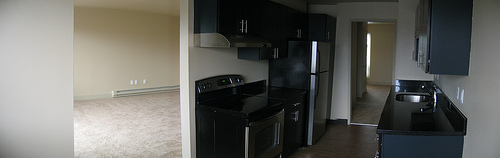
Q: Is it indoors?
A: Yes, it is indoors.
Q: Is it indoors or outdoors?
A: It is indoors.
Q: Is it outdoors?
A: No, it is indoors.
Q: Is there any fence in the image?
A: No, there are no fences.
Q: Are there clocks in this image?
A: No, there are no clocks.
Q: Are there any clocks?
A: No, there are no clocks.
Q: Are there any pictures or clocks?
A: No, there are no clocks or pictures.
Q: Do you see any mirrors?
A: No, there are no mirrors.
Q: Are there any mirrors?
A: No, there are no mirrors.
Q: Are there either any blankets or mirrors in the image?
A: No, there are no mirrors or blankets.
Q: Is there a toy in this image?
A: No, there are no toys.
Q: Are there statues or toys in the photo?
A: No, there are no toys or statues.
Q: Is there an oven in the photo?
A: Yes, there is an oven.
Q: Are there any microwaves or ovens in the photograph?
A: Yes, there is an oven.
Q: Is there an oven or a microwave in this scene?
A: Yes, there is an oven.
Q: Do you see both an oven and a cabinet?
A: Yes, there are both an oven and a cabinet.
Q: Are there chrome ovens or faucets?
A: Yes, there is a chrome oven.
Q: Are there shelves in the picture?
A: No, there are no shelves.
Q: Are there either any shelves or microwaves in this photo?
A: No, there are no shelves or microwaves.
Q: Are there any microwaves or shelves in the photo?
A: No, there are no shelves or microwaves.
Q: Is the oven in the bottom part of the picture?
A: Yes, the oven is in the bottom of the image.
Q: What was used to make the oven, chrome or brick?
A: The oven is made of chrome.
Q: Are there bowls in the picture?
A: No, there are no bowls.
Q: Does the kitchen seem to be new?
A: Yes, the kitchen is new.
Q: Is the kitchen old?
A: No, the kitchen is new.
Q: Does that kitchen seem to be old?
A: No, the kitchen is new.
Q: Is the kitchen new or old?
A: The kitchen is new.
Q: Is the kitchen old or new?
A: The kitchen is new.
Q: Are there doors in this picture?
A: Yes, there are doors.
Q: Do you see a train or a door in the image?
A: Yes, there are doors.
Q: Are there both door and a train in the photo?
A: No, there are doors but no trains.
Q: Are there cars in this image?
A: No, there are no cars.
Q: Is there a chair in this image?
A: No, there are no chairs.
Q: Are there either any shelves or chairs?
A: No, there are no chairs or shelves.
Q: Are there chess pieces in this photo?
A: No, there are no chess pieces.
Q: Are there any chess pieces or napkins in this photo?
A: No, there are no chess pieces or napkins.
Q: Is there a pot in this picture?
A: No, there are no pots.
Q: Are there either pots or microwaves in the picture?
A: No, there are no pots or microwaves.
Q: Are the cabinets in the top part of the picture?
A: Yes, the cabinets are in the top of the image.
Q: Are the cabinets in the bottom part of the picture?
A: No, the cabinets are in the top of the image.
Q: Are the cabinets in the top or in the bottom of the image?
A: The cabinets are in the top of the image.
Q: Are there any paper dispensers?
A: No, there are no paper dispensers.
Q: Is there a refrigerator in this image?
A: Yes, there is a refrigerator.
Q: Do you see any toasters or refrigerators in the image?
A: Yes, there is a refrigerator.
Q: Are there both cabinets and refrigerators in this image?
A: Yes, there are both a refrigerator and cabinets.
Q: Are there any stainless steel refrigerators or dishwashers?
A: Yes, there is a stainless steel refrigerator.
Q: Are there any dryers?
A: No, there are no dryers.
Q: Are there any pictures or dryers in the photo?
A: No, there are no dryers or pictures.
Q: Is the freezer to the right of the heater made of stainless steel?
A: Yes, the fridge is made of stainless steel.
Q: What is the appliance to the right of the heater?
A: The appliance is a refrigerator.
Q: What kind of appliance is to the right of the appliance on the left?
A: The appliance is a refrigerator.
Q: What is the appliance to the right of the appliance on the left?
A: The appliance is a refrigerator.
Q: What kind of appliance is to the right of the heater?
A: The appliance is a refrigerator.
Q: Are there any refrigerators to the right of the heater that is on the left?
A: Yes, there is a refrigerator to the right of the heater.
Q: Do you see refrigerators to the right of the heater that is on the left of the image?
A: Yes, there is a refrigerator to the right of the heater.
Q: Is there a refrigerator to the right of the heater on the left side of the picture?
A: Yes, there is a refrigerator to the right of the heater.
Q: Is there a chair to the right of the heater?
A: No, there is a refrigerator to the right of the heater.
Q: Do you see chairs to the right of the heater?
A: No, there is a refrigerator to the right of the heater.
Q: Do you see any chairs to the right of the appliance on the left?
A: No, there is a refrigerator to the right of the heater.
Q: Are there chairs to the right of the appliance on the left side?
A: No, there is a refrigerator to the right of the heater.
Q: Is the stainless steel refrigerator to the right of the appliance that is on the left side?
A: Yes, the freezer is to the right of the heater.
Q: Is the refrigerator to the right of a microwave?
A: No, the refrigerator is to the right of the heater.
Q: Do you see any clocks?
A: No, there are no clocks.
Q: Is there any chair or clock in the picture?
A: No, there are no clocks or chairs.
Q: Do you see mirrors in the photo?
A: No, there are no mirrors.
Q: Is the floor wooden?
A: Yes, the floor is wooden.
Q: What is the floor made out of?
A: The floor is made of wood.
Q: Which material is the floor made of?
A: The floor is made of wood.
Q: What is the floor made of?
A: The floor is made of wood.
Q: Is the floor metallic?
A: No, the floor is wooden.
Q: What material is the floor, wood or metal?
A: The floor is made of wood.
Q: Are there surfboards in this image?
A: No, there are no surfboards.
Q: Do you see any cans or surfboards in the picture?
A: No, there are no surfboards or cans.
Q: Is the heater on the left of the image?
A: Yes, the heater is on the left of the image.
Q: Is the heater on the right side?
A: No, the heater is on the left of the image.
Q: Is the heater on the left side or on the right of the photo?
A: The heater is on the left of the image.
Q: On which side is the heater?
A: The heater is on the left of the image.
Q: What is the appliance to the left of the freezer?
A: The appliance is a heater.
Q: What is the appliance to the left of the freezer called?
A: The appliance is a heater.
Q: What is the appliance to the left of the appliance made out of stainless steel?
A: The appliance is a heater.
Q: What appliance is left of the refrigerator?
A: The appliance is a heater.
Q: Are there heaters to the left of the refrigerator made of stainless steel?
A: Yes, there is a heater to the left of the freezer.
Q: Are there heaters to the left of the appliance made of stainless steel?
A: Yes, there is a heater to the left of the freezer.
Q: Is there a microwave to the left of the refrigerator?
A: No, there is a heater to the left of the refrigerator.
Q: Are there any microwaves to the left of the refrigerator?
A: No, there is a heater to the left of the refrigerator.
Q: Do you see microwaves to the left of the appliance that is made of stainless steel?
A: No, there is a heater to the left of the refrigerator.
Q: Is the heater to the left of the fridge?
A: Yes, the heater is to the left of the fridge.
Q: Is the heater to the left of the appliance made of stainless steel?
A: Yes, the heater is to the left of the fridge.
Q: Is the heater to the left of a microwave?
A: No, the heater is to the left of the fridge.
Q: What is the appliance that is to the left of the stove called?
A: The appliance is a heater.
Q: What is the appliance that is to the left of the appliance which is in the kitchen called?
A: The appliance is a heater.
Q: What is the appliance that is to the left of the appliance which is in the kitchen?
A: The appliance is a heater.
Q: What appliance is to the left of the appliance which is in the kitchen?
A: The appliance is a heater.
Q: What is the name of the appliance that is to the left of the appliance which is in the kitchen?
A: The appliance is a heater.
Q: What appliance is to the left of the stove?
A: The appliance is a heater.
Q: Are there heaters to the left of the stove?
A: Yes, there is a heater to the left of the stove.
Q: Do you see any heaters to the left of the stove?
A: Yes, there is a heater to the left of the stove.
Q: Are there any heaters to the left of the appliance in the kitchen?
A: Yes, there is a heater to the left of the stove.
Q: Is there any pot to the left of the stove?
A: No, there is a heater to the left of the stove.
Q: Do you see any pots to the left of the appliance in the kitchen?
A: No, there is a heater to the left of the stove.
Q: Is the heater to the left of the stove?
A: Yes, the heater is to the left of the stove.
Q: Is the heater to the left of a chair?
A: No, the heater is to the left of the stove.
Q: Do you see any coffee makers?
A: No, there are no coffee makers.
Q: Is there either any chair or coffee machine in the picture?
A: No, there are no coffee makers or chairs.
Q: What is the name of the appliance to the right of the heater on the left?
A: The appliance is a stove.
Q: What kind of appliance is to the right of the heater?
A: The appliance is a stove.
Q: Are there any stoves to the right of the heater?
A: Yes, there is a stove to the right of the heater.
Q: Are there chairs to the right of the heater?
A: No, there is a stove to the right of the heater.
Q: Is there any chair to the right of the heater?
A: No, there is a stove to the right of the heater.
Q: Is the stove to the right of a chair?
A: No, the stove is to the right of the heater.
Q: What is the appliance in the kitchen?
A: The appliance is a stove.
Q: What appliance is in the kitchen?
A: The appliance is a stove.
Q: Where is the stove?
A: The stove is in the kitchen.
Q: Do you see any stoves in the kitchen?
A: Yes, there is a stove in the kitchen.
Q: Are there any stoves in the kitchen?
A: Yes, there is a stove in the kitchen.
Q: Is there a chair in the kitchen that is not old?
A: No, there is a stove in the kitchen.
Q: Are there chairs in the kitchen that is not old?
A: No, there is a stove in the kitchen.